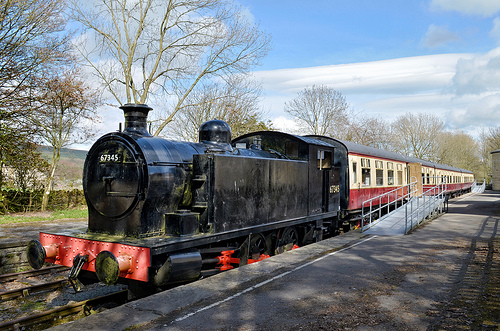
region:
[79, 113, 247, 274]
black engine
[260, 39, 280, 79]
white clouds in blue sky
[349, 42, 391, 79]
white clouds in blue sky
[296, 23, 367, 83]
white clouds in blue sky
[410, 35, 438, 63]
white clouds in blue sky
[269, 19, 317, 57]
white clouds in blue sky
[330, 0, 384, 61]
white clouds in blue sky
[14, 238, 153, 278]
red in front of train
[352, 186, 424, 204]
red bottom on the car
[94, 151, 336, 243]
black engine in the front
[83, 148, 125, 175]
number on the train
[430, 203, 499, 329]
tracks on the ground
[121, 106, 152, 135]
smoke stack on top of train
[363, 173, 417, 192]
windows on the train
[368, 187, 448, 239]
ramp on the platform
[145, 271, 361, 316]
white line on the pavement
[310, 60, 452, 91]
clouds in the sky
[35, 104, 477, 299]
a train on train tracks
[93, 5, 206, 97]
the branches of a tree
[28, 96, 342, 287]
a black engine of a train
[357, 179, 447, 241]
a ramp to load the passengers of a train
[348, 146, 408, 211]
a car of a train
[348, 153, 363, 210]
the door of a train car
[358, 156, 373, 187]
the window of a train car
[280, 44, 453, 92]
a cloud in the sky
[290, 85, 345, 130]
the branches of a tree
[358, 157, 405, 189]
the windows of a train car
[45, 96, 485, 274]
train on the track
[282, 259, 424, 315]
concrete near rail track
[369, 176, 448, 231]
ramp with rails on it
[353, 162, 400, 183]
windows on the train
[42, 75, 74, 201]
small tree in field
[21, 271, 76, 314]
tracks train is on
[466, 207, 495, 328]
reflection of a track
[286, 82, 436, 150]
tops of trees without branches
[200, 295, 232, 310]
white line on ground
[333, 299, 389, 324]
leaves on the ground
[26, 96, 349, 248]
the locomotive of a train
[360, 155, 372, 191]
the window of a train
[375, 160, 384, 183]
the window of a train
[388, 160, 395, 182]
the window of a train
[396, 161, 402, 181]
the window of a train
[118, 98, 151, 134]
the smokestack of a locomotive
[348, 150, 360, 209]
the door of a train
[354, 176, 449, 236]
a ramp in front of a train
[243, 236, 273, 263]
a wheel on a locomotive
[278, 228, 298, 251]
a wheel on a locomotive